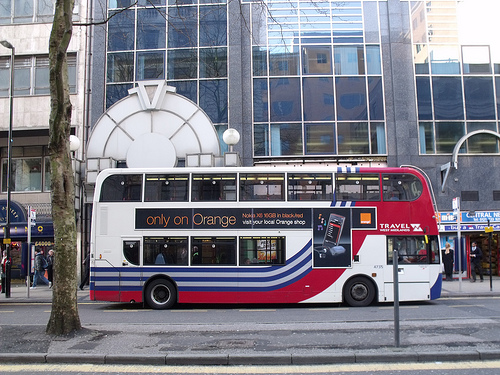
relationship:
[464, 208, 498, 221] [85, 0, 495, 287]
lettering wearing building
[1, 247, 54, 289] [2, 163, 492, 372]
people in street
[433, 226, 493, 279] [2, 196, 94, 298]
pedestrians in background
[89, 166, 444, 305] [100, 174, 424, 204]
bus has windows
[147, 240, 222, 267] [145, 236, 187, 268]
passengers seen in window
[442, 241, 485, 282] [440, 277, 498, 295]
pedestrians on sidewalk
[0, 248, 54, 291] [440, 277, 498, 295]
people on sidewalk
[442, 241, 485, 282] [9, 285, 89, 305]
pedestrians on sidewalk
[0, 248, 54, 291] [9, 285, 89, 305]
people on sidewalk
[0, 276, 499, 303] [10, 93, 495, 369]
sidewalk on street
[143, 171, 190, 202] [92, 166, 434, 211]
window on upper level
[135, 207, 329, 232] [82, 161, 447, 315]
advertisement on bus